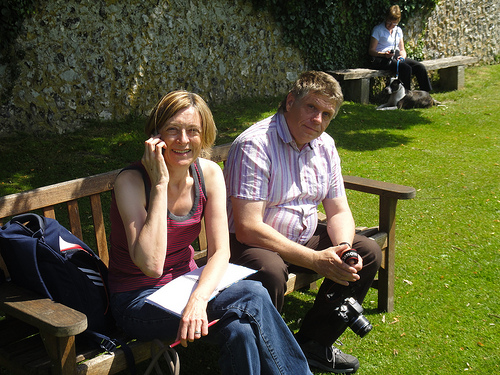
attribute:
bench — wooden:
[11, 145, 406, 337]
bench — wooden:
[1, 147, 411, 372]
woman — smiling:
[118, 90, 308, 370]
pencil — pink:
[169, 317, 220, 351]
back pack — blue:
[4, 210, 124, 350]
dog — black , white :
[390, 70, 457, 156]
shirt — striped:
[221, 109, 346, 250]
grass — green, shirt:
[407, 140, 498, 276]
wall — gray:
[1, 3, 499, 133]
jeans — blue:
[116, 279, 314, 373]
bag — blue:
[1, 207, 137, 332]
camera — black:
[327, 281, 376, 340]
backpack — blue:
[2, 210, 129, 340]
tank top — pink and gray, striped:
[103, 153, 211, 302]